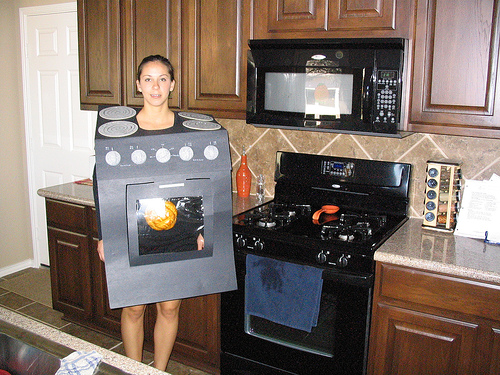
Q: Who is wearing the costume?
A: The girl.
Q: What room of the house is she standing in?
A: Kitchen.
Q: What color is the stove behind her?
A: Black.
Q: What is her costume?
A: A stove.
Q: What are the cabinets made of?
A: Wood.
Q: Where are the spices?
A: In a rack on the counter.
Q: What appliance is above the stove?
A: Microwave.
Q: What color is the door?
A: White.